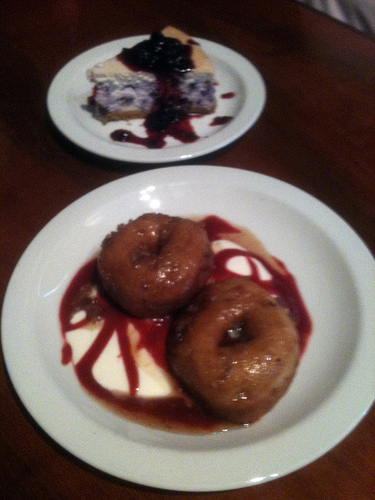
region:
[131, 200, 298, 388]
Two doughnuts on a white plate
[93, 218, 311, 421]
Two brown doughnuts on a white plate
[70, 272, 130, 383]
Brown sauce on white plate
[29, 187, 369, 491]
White plate with doughnuts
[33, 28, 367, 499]
Two white plates with food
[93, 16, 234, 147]
White desert with blue sauce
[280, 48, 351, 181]
Brown wood table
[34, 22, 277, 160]
Small white plate with blue and white food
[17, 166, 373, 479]
Large white plate with twp doughnuts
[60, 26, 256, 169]
White pie with blue filling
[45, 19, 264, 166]
a piece of cake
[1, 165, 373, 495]
dough nuts on a round plate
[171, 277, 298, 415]
a round cake dough nut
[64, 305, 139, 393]
a red sauce on the plate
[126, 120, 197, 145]
a blackberry syrup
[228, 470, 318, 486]
a refection on a plate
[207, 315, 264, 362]
a hole in the dough nut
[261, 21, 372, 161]
a brown wooden table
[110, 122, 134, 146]
black berry's in the syrup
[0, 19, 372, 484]
two plates of desert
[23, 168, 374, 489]
two donuts on plate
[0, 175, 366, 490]
white plate with donuts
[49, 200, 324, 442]
red sauce over donuts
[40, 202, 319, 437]
red icing swirled on plate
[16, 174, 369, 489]
plate is white and round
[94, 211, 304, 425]
donuts are glazed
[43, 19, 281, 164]
two cheesecakes on plate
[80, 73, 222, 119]
blueberry cheescake on plate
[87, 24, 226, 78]
cheesecake on plate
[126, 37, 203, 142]
raspberry topping on cheesecake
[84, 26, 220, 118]
a piece of cheesecake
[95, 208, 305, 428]
a pair of donuts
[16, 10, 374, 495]
a dark wood table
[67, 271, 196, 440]
a thick red sauce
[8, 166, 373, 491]
a plain white plate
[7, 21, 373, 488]
a pair of round plates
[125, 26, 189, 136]
a blueberry sauce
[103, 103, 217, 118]
a graham cracker crust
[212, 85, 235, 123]
a few droplets of sauce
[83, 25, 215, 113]
a creamy blueberry dessert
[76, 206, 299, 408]
two glazed donuts sitting on a white plate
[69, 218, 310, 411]
the sauce sitting under the donuts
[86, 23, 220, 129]
a slice of cheesecake sitting on the plate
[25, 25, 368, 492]
the plates the desserts are sitting on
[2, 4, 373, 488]
the table the plates are sitting on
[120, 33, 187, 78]
some fruit on top of the cheesecake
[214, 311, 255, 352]
the center of the donut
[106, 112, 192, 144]
some fruit sitting on the plate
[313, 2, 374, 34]
someone standing by the table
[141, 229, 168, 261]
the center of the other donut